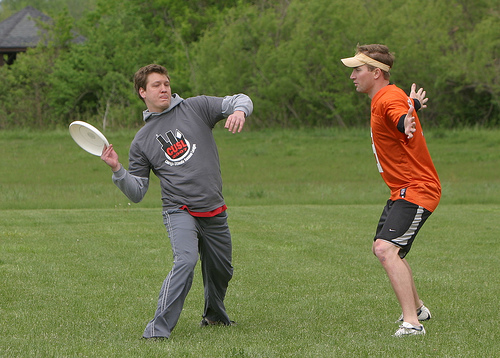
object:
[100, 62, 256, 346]
man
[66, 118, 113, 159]
frisbee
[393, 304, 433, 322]
right shoe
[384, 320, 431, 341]
left shoe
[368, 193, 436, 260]
shorts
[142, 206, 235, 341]
pants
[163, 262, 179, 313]
stripe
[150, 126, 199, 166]
logo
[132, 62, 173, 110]
head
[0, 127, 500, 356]
grass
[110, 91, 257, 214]
sweater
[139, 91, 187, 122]
hood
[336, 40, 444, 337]
man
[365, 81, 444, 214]
jersey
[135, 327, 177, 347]
feet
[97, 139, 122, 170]
right hand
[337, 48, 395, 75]
visor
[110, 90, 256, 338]
sweatsuit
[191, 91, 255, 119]
left arm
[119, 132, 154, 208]
right arm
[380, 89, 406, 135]
arms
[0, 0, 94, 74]
structure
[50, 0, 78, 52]
trees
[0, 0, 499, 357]
picture